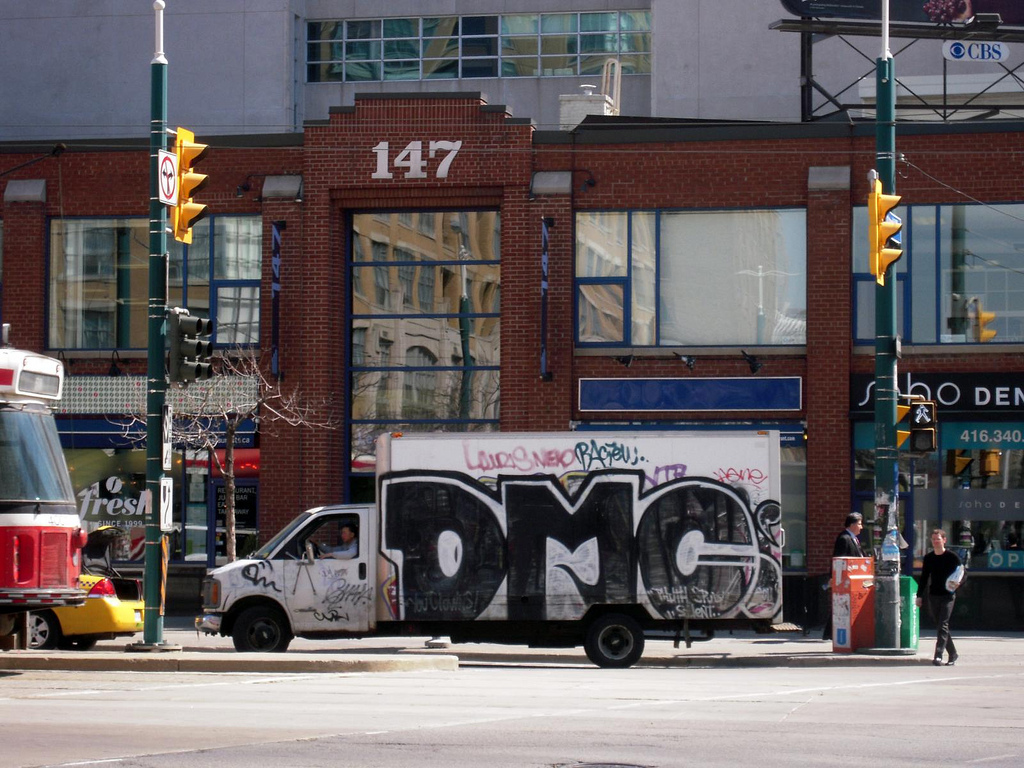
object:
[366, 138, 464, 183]
number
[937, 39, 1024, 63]
cbs sign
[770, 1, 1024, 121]
billboard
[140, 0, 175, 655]
pole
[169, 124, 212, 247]
traffic light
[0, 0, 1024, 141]
building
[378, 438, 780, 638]
graffiti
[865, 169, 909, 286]
traffic light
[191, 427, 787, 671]
truck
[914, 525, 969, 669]
man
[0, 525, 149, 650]
taxi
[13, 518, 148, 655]
taxi truck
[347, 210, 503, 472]
wall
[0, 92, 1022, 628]
building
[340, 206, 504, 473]
reflection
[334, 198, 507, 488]
window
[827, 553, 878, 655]
box